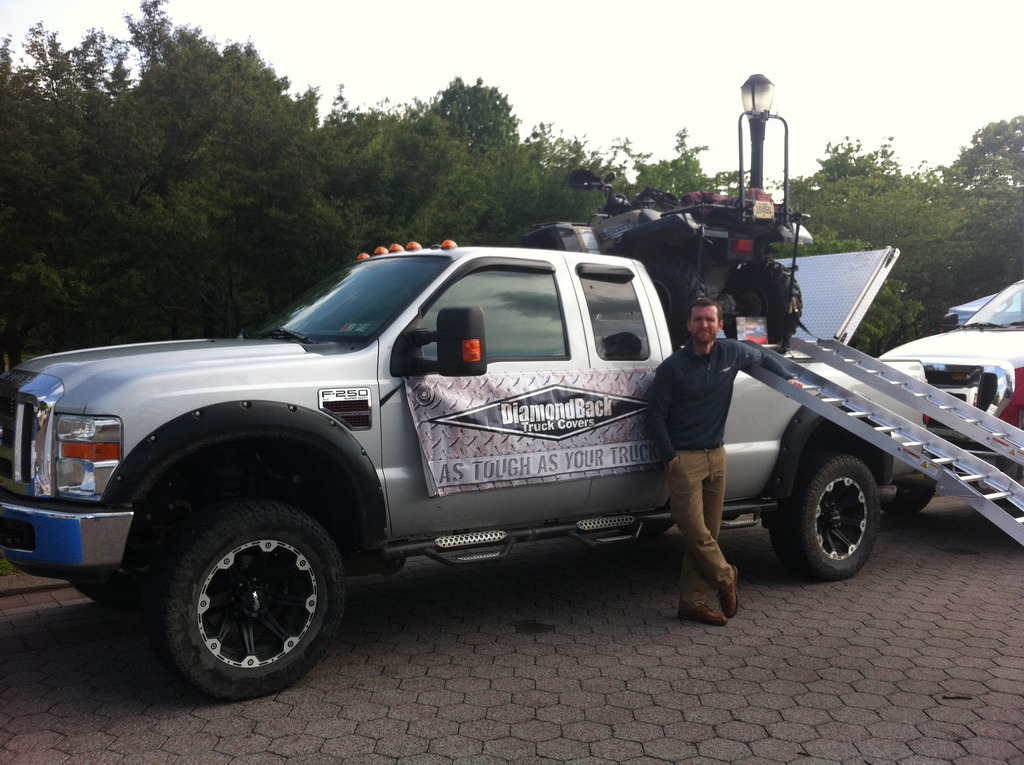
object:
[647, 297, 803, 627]
he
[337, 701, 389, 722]
tile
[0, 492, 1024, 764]
floor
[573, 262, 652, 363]
window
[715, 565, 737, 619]
shoe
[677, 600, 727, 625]
shoe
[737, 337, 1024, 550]
ramp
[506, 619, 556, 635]
stain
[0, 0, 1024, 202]
sky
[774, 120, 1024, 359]
trees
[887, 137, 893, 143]
leaves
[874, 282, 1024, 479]
suv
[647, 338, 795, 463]
shirt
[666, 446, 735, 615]
pants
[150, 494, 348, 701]
tire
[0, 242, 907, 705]
truck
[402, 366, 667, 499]
banner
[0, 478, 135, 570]
bumper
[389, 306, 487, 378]
mirror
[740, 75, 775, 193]
street light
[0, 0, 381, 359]
trees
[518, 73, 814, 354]
four wheeler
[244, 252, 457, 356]
windshield